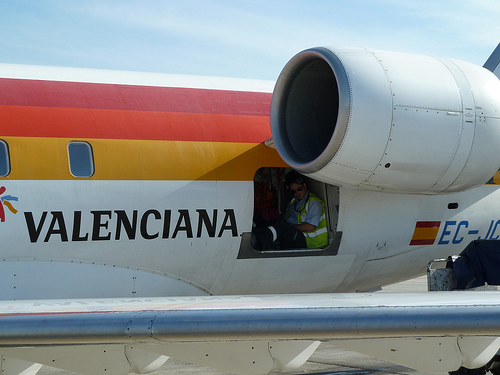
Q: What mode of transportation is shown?
A: Airplane.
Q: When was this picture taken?
A: Daytime.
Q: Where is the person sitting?
A: In the plane.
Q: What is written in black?
A: Valenciana.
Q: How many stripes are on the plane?
A: 3.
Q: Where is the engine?
A: Top right corner.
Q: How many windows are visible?
A: 2.